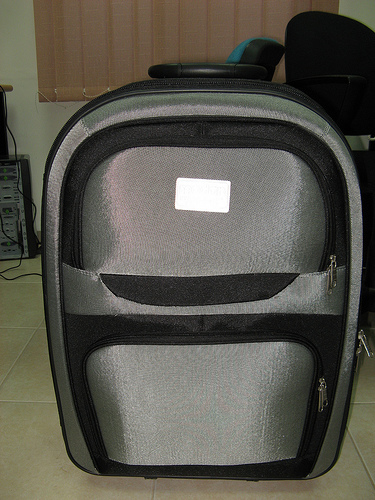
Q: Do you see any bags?
A: Yes, there is a bag.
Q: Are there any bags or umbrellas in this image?
A: Yes, there is a bag.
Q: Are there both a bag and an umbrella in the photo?
A: No, there is a bag but no umbrellas.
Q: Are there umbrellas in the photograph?
A: No, there are no umbrellas.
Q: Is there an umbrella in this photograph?
A: No, there are no umbrellas.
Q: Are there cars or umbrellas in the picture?
A: No, there are no umbrellas or cars.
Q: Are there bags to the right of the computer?
A: Yes, there is a bag to the right of the computer.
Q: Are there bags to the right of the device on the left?
A: Yes, there is a bag to the right of the computer.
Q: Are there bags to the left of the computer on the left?
A: No, the bag is to the right of the computer.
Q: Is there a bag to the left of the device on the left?
A: No, the bag is to the right of the computer.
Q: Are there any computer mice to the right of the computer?
A: No, there is a bag to the right of the computer.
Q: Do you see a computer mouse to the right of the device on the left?
A: No, there is a bag to the right of the computer.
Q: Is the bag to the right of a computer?
A: Yes, the bag is to the right of a computer.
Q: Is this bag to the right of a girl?
A: No, the bag is to the right of a computer.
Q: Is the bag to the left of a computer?
A: No, the bag is to the right of a computer.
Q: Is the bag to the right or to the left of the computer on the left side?
A: The bag is to the right of the computer.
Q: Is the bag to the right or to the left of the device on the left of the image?
A: The bag is to the right of the computer.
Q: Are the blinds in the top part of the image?
A: Yes, the blinds are in the top of the image.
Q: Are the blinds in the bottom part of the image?
A: No, the blinds are in the top of the image.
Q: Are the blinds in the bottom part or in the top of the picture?
A: The blinds are in the top of the image.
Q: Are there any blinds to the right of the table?
A: Yes, there are blinds to the right of the table.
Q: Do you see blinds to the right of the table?
A: Yes, there are blinds to the right of the table.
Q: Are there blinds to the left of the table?
A: No, the blinds are to the right of the table.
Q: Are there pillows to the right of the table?
A: No, there are blinds to the right of the table.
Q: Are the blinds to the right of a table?
A: Yes, the blinds are to the right of a table.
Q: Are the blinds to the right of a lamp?
A: No, the blinds are to the right of a table.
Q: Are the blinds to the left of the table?
A: No, the blinds are to the right of the table.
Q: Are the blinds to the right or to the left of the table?
A: The blinds are to the right of the table.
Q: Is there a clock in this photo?
A: No, there are no clocks.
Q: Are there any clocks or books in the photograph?
A: No, there are no clocks or books.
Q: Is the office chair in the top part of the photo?
A: Yes, the office chair is in the top of the image.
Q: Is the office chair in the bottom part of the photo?
A: No, the office chair is in the top of the image.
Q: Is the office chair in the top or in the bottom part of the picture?
A: The office chair is in the top of the image.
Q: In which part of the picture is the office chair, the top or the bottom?
A: The office chair is in the top of the image.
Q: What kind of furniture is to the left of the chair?
A: The piece of furniture is an office chair.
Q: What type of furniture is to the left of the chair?
A: The piece of furniture is an office chair.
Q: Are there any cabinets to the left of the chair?
A: No, there is an office chair to the left of the chair.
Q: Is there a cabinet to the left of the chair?
A: No, there is an office chair to the left of the chair.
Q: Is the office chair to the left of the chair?
A: Yes, the office chair is to the left of the chair.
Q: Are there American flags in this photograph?
A: No, there are no American flags.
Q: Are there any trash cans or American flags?
A: No, there are no American flags or trash cans.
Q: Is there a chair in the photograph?
A: Yes, there is a chair.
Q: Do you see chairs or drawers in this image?
A: Yes, there is a chair.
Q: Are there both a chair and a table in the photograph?
A: Yes, there are both a chair and a table.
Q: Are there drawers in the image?
A: No, there are no drawers.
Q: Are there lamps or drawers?
A: No, there are no drawers or lamps.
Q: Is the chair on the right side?
A: Yes, the chair is on the right of the image.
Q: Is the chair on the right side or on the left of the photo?
A: The chair is on the right of the image.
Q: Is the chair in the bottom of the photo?
A: No, the chair is in the top of the image.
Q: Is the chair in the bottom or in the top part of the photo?
A: The chair is in the top of the image.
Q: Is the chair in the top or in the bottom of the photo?
A: The chair is in the top of the image.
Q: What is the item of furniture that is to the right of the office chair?
A: The piece of furniture is a chair.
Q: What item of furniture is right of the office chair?
A: The piece of furniture is a chair.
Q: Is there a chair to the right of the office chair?
A: Yes, there is a chair to the right of the office chair.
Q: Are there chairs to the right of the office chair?
A: Yes, there is a chair to the right of the office chair.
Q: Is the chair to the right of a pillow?
A: No, the chair is to the right of the office chair.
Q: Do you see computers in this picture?
A: Yes, there is a computer.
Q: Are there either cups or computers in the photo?
A: Yes, there is a computer.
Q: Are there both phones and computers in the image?
A: No, there is a computer but no phones.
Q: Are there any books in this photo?
A: No, there are no books.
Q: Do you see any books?
A: No, there are no books.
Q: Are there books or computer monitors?
A: No, there are no books or computer monitors.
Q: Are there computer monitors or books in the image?
A: No, there are no books or computer monitors.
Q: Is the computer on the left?
A: Yes, the computer is on the left of the image.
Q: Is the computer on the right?
A: No, the computer is on the left of the image.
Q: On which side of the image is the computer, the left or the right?
A: The computer is on the left of the image.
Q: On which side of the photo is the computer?
A: The computer is on the left of the image.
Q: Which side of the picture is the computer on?
A: The computer is on the left of the image.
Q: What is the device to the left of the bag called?
A: The device is a computer.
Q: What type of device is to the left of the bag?
A: The device is a computer.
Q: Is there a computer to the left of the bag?
A: Yes, there is a computer to the left of the bag.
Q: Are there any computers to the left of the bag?
A: Yes, there is a computer to the left of the bag.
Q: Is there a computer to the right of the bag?
A: No, the computer is to the left of the bag.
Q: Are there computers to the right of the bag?
A: No, the computer is to the left of the bag.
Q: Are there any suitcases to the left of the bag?
A: No, there is a computer to the left of the bag.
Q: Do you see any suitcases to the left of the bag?
A: No, there is a computer to the left of the bag.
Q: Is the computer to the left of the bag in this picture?
A: Yes, the computer is to the left of the bag.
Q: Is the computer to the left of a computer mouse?
A: No, the computer is to the left of the bag.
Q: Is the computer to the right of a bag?
A: No, the computer is to the left of a bag.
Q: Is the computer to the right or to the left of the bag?
A: The computer is to the left of the bag.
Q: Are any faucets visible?
A: No, there are no faucets.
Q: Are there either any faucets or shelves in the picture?
A: No, there are no faucets or shelves.